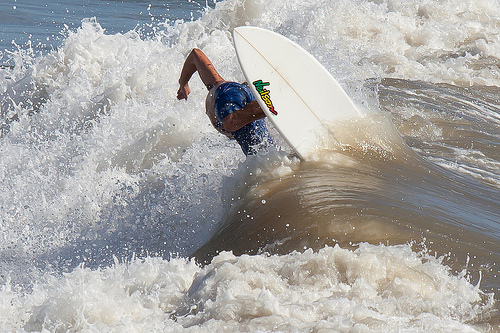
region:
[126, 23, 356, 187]
person surfing in the ocean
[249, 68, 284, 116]
writing on the board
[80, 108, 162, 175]
white waves in the ocean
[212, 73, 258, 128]
blue shorts on man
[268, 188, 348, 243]
wave in the water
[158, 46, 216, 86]
arm of the man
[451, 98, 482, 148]
water behind the man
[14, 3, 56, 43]
still water in the ocean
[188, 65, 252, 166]
man falling in the water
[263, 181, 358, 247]
top of the wave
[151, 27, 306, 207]
person in the water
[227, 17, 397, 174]
board sticking out of the water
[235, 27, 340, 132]
thin line running along the center of the board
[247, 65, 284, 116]
small logo on the board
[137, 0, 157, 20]
droplets of water coming off the wave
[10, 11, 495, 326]
wave engulfing a person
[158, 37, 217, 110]
arm is bent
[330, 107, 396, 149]
water splashing up arond the board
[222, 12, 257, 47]
pointy tip of the board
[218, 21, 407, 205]
white board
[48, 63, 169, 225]
The waves of the water is white.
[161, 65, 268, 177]
A person in the water.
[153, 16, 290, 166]
A man on the surfboard.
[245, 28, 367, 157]
The surfboard is white.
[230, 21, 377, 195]
The surboard is on top of the wave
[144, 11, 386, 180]
The surfer is riding the wave.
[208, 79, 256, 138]
The surfer has on blue shorts.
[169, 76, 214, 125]
The surfer is shirtless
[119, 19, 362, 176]
The surfboard and surfer is in the water.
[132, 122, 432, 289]
The wave is high.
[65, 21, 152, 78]
white water of splashing wave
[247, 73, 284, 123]
logo on bottom of surfboard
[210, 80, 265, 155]
blue shorts on surfer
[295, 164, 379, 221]
reflection on water surface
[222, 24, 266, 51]
tip of white board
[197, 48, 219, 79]
light reflection on arm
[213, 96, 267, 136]
bent leg of surfer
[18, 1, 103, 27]
surface of blue water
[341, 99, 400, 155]
water splashing from surfboard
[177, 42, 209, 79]
elbow of bent arm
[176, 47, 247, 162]
this is a man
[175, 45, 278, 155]
the man is sea surfing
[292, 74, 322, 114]
the board is white in color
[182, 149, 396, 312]
this is the waves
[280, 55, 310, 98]
the board is white in color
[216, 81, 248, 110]
the short is blue in color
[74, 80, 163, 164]
the water is splashy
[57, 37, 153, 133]
the splash is white in color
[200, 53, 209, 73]
this is the hand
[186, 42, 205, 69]
the elbow is bent